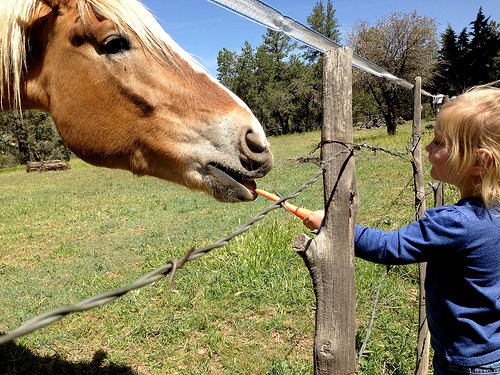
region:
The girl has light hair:
[419, 67, 497, 202]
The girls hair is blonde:
[403, 67, 499, 200]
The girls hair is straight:
[404, 57, 495, 205]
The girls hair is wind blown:
[394, 48, 496, 203]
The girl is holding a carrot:
[243, 175, 361, 247]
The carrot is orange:
[247, 178, 344, 228]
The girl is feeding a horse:
[154, 60, 371, 307]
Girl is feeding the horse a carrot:
[158, 70, 356, 248]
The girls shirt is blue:
[327, 188, 492, 360]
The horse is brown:
[16, 7, 368, 209]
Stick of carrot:
[256, 187, 312, 222]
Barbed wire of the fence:
[7, 210, 274, 305]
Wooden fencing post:
[308, 64, 370, 373]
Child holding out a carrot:
[270, 78, 479, 369]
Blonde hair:
[437, 73, 480, 191]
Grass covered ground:
[2, 180, 154, 270]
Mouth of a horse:
[200, 152, 270, 207]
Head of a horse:
[42, 0, 262, 205]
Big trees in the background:
[253, 26, 410, 124]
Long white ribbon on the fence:
[234, 3, 444, 99]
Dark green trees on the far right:
[435, 6, 497, 112]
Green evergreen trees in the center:
[200, 2, 372, 156]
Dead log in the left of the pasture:
[10, 146, 79, 190]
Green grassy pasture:
[1, 105, 491, 373]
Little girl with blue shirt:
[400, 75, 498, 374]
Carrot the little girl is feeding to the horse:
[228, 163, 374, 276]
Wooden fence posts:
[272, 31, 499, 373]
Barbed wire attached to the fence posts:
[5, 142, 494, 370]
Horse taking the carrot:
[0, 0, 291, 232]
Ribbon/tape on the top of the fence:
[208, 0, 498, 98]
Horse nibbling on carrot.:
[100, 6, 320, 224]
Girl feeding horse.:
[249, 85, 496, 266]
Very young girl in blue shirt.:
[413, 86, 498, 321]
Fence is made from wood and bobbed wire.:
[267, 115, 400, 192]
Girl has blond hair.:
[407, 87, 499, 184]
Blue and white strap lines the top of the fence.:
[272, 4, 365, 92]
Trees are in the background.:
[235, 19, 344, 124]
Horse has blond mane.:
[3, 0, 185, 117]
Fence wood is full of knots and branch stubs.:
[293, 38, 356, 370]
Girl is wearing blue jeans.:
[415, 97, 497, 373]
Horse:
[15, 4, 324, 223]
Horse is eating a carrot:
[184, 86, 317, 250]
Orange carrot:
[227, 165, 304, 217]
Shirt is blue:
[300, 72, 490, 372]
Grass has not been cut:
[88, 192, 373, 341]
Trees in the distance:
[195, 15, 425, 160]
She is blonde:
[417, 70, 497, 201]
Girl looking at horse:
[417, 76, 497, 206]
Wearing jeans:
[423, 331, 474, 371]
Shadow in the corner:
[4, 300, 139, 374]